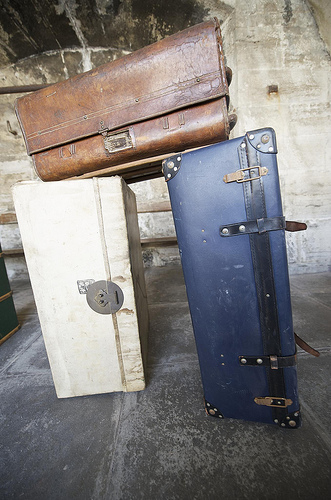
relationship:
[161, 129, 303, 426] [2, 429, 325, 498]
suitcase on ground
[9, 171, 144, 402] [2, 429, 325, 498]
suitcase on ground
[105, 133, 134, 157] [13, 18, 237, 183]
strap on suitcase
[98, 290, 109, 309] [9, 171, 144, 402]
keyhole of suitcase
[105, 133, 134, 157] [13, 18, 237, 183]
strap of suitcase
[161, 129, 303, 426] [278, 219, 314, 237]
suitcase has strap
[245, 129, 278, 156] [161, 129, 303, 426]
corner of suitcase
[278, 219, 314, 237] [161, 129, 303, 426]
strap on suitcase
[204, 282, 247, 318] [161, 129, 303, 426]
rivet on suitcase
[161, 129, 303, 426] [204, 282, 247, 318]
suitcase has rivet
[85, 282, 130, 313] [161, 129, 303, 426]
clasp on suitcase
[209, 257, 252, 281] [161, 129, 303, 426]
mark on suitcase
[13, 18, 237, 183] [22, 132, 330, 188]
suitcase on top